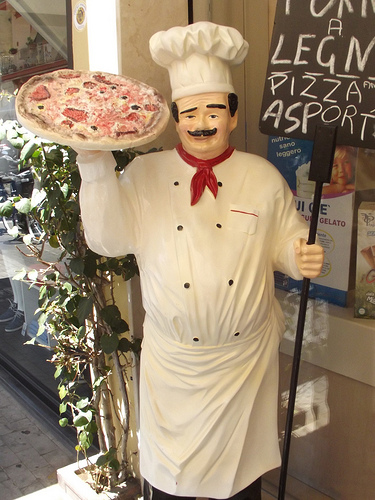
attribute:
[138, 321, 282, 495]
apron — white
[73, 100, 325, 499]
body — black, life sized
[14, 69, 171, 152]
pizza — round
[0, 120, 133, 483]
plant — potted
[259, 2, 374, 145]
writing — white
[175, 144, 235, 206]
scarf — red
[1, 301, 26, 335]
shoes — grey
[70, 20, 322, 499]
chef — male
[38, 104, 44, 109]
olives — black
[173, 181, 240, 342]
buttons — black